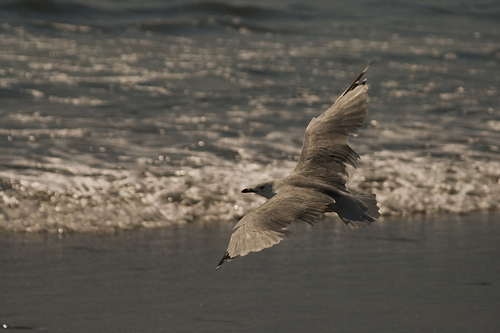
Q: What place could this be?
A: It is a beach.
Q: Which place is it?
A: It is a beach.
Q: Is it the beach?
A: Yes, it is the beach.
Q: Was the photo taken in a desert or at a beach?
A: It was taken at a beach.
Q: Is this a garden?
A: No, it is a beach.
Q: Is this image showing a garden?
A: No, the picture is showing a beach.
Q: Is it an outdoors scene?
A: Yes, it is outdoors.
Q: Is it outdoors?
A: Yes, it is outdoors.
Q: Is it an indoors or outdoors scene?
A: It is outdoors.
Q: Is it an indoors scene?
A: No, it is outdoors.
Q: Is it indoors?
A: No, it is outdoors.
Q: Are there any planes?
A: No, there are no planes.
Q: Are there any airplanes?
A: No, there are no airplanes.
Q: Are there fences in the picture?
A: No, there are no fences.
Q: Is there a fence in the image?
A: No, there are no fences.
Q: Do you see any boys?
A: No, there are no boys.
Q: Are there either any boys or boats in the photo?
A: No, there are no boys or boats.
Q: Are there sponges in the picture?
A: No, there are no sponges.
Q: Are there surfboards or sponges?
A: No, there are no sponges or surfboards.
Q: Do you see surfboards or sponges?
A: No, there are no sponges or surfboards.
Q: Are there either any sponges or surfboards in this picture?
A: No, there are no sponges or surfboards.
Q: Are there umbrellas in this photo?
A: No, there are no umbrellas.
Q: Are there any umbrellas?
A: No, there are no umbrellas.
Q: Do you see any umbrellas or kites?
A: No, there are no umbrellas or kites.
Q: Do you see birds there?
A: Yes, there is a bird.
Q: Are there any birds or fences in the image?
A: Yes, there is a bird.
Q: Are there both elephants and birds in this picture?
A: No, there is a bird but no elephants.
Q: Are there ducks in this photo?
A: No, there are no ducks.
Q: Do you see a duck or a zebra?
A: No, there are no ducks or zebras.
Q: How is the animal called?
A: The animal is a bird.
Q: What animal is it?
A: The animal is a bird.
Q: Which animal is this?
A: This is a bird.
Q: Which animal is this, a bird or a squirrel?
A: This is a bird.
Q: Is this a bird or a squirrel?
A: This is a bird.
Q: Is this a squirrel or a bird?
A: This is a bird.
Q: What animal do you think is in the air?
A: The bird is in the air.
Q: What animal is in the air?
A: The bird is in the air.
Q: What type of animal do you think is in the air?
A: The animal is a bird.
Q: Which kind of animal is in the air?
A: The animal is a bird.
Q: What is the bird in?
A: The bird is in the air.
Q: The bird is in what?
A: The bird is in the air.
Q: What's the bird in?
A: The bird is in the air.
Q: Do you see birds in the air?
A: Yes, there is a bird in the air.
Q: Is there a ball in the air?
A: No, there is a bird in the air.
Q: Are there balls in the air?
A: No, there is a bird in the air.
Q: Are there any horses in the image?
A: No, there are no horses.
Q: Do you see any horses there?
A: No, there are no horses.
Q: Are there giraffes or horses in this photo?
A: No, there are no horses or giraffes.